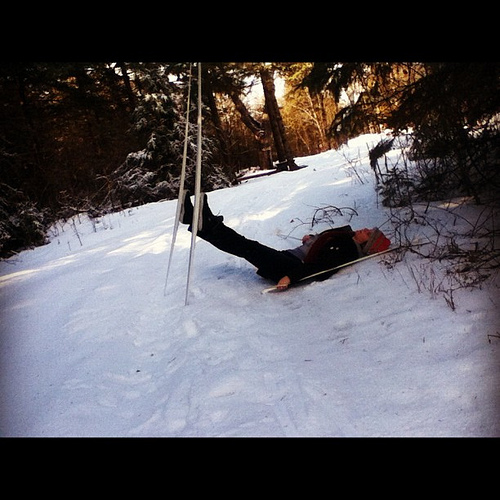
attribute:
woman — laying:
[188, 207, 387, 265]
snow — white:
[110, 306, 171, 342]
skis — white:
[163, 92, 208, 303]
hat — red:
[371, 238, 398, 259]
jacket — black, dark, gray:
[310, 242, 355, 267]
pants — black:
[225, 239, 272, 268]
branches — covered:
[103, 75, 164, 116]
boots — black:
[173, 193, 218, 228]